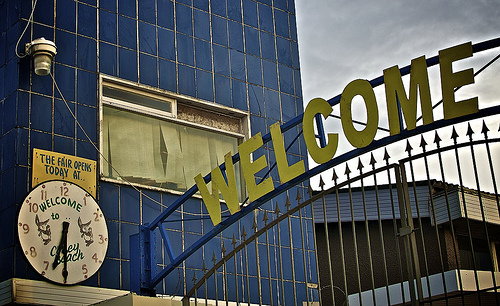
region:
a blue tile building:
[82, 0, 283, 77]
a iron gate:
[207, 232, 493, 284]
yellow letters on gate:
[201, 57, 489, 197]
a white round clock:
[14, 171, 109, 283]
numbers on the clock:
[90, 249, 99, 269]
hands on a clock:
[47, 219, 80, 277]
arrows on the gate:
[352, 152, 391, 173]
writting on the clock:
[39, 196, 90, 263]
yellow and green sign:
[32, 152, 102, 183]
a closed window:
[104, 77, 230, 184]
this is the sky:
[308, 8, 375, 48]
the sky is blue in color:
[319, 14, 370, 45]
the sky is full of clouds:
[311, 10, 418, 50]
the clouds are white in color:
[303, 7, 329, 32]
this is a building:
[76, 4, 291, 272]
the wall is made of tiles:
[183, 7, 244, 82]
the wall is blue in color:
[167, 17, 287, 87]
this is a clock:
[16, 175, 110, 290]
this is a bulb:
[29, 35, 59, 83]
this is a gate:
[241, 163, 498, 300]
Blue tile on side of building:
[162, 33, 292, 105]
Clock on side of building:
[6, 158, 112, 289]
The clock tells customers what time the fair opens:
[31, 138, 129, 298]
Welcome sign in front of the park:
[161, 83, 498, 165]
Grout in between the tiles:
[164, 40, 202, 92]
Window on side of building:
[92, 57, 254, 220]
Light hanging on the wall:
[20, 33, 85, 85]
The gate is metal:
[308, 202, 415, 302]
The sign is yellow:
[184, 92, 343, 209]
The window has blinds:
[90, 90, 259, 190]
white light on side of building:
[17, 30, 76, 100]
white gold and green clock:
[0, 183, 107, 301]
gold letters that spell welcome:
[199, 37, 475, 225]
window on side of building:
[95, 92, 252, 207]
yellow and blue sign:
[6, 148, 113, 203]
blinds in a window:
[70, 126, 227, 206]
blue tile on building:
[145, 21, 280, 83]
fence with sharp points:
[223, 144, 487, 304]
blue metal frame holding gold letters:
[157, 43, 478, 259]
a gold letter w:
[185, 148, 238, 230]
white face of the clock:
[23, 190, 99, 272]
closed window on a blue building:
[98, 73, 259, 215]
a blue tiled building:
[0, 15, 337, 298]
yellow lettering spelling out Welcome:
[204, 58, 486, 221]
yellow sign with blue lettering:
[15, 145, 105, 202]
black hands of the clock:
[48, 211, 74, 283]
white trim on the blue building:
[6, 265, 269, 304]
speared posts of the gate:
[180, 148, 499, 298]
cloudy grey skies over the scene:
[321, 17, 496, 62]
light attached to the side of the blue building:
[0, 25, 67, 105]